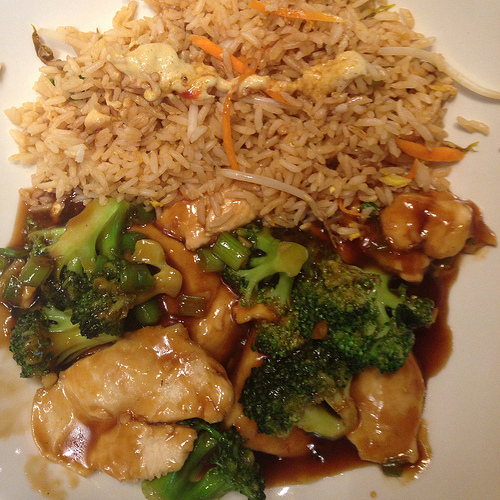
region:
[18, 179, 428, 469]
Broccoli pieces in sauce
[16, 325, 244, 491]
a piece of chicken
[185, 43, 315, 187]
Small slices of carrots in rice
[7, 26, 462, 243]
White rice next to veggies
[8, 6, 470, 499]
Food on a white plate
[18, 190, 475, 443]
A brown sauce on vegetables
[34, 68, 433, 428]
A chinese dish of food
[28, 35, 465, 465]
a plate of chinese food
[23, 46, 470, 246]
White rice on white plate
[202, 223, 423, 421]
Green broccoli chunks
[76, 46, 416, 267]
a rice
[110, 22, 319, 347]
a rice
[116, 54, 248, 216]
a rice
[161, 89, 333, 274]
a rice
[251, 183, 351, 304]
a rice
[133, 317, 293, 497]
Chicken with sauce on it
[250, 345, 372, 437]
Broccoli that has been steamed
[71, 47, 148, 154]
The rice is fried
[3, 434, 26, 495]
The plate is white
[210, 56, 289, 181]
Carrots in the rice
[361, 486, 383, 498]
Sauce on the plate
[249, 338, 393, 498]
The broccoli has sauce on it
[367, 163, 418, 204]
Small piece of egg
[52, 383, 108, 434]
The sauce is on the chicken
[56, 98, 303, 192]
The rice has sauce on it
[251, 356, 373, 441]
the broccoli is green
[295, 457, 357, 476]
the sauce is brwon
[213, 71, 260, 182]
the carrot is orange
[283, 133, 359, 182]
the rice is a tan color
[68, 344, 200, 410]
the chicken has sauce on it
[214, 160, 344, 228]
the sprout is white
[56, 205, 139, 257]
the stem of the broccoli is green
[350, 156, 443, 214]
the rice has something yellow in it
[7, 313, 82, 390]
this broccoli has brown sauce on it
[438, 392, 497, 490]
the dish that the food is on is white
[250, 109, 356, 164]
Rice.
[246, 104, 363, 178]
The rice is off white.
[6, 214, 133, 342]
The broccoli is green.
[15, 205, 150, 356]
Broccoli is in the dish.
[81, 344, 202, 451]
Meat is in the dish.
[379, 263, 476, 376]
Sauce is on the food.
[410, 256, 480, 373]
The sauce is brown.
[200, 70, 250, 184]
Pieces of carrot are on the dish.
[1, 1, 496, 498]
The plate is white.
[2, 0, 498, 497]
The food is on a plate.